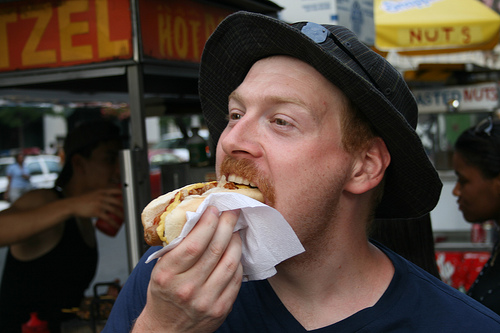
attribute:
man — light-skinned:
[104, 21, 496, 331]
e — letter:
[58, 3, 91, 63]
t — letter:
[443, 23, 458, 43]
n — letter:
[408, 26, 420, 42]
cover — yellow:
[372, 0, 499, 54]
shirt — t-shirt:
[122, 226, 496, 326]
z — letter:
[15, 9, 73, 76]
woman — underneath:
[0, 101, 134, 327]